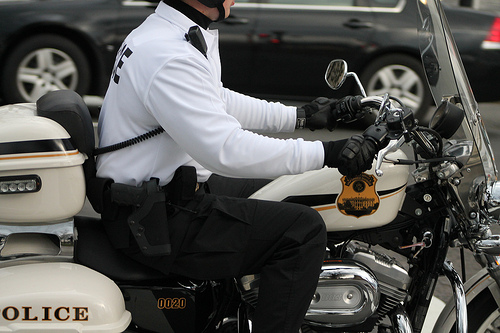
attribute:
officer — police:
[90, 0, 384, 330]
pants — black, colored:
[118, 183, 324, 326]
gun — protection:
[108, 175, 170, 256]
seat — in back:
[19, 85, 111, 209]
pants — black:
[97, 163, 324, 329]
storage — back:
[1, 98, 84, 223]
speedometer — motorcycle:
[428, 85, 469, 135]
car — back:
[1, 0, 498, 140]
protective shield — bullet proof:
[415, 0, 497, 185]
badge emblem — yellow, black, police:
[335, 175, 383, 220]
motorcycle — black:
[8, 22, 498, 325]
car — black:
[258, 4, 440, 101]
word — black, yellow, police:
[0, 303, 90, 325]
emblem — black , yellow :
[307, 79, 409, 267]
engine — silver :
[273, 223, 378, 320]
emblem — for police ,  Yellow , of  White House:
[335, 172, 380, 220]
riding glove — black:
[318, 135, 375, 175]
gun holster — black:
[106, 179, 171, 258]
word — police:
[0, 301, 90, 323]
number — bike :
[153, 287, 185, 313]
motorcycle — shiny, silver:
[8, 65, 483, 316]